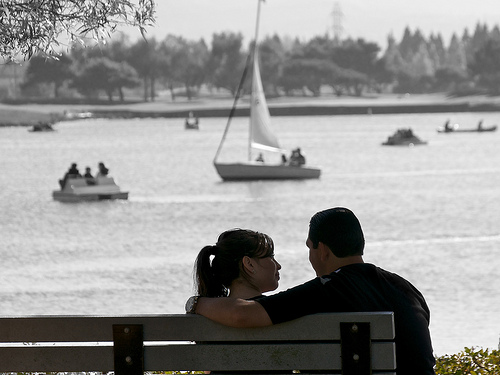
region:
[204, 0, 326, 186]
a few people in a sailboat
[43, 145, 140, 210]
three people in a paddleboat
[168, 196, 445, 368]
two people talking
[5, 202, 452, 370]
two people sitting on a bench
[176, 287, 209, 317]
a very large watch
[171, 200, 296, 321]
a woman wearing her hair in a pony tail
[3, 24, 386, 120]
many low trees with flat tops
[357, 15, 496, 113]
pointy triangular evergreen trees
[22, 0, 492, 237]
six boats on a sparkly lake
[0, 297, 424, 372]
a long park bench by a lake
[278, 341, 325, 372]
part of a bench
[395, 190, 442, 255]
part of a water body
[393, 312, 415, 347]
part of a black top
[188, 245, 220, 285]
hair of a woman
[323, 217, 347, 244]
hair of a man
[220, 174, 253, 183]
base of a boat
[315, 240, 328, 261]
left ear of a man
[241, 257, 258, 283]
right ear of the lady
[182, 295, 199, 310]
part of a wrist watch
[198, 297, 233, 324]
left arm of the man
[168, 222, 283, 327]
the woman is gazing at the man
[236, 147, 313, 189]
there are 4 people on the sailboat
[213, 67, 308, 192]
there is a sailboat on the water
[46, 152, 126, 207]
these people are in a paddle boat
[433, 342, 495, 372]
the bush is near the couple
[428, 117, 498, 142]
there are two people rowing the canoe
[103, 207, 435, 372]
the couple is sitting on a bench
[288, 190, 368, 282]
the man is looking out over the water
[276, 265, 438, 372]
the man is wearing a black shirt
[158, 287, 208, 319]
the man is wearing a big watch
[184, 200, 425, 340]
two people sitting on a bench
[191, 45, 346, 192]
a small sailboat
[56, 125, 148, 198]
three people riding on a boat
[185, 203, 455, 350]
a woman looking at a man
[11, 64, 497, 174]
several boats on the water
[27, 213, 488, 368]
a bench by the water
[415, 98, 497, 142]
two people in a row boat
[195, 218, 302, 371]
a woman with a ponytail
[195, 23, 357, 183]
a boat with people sailing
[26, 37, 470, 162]
multiple trees by the lake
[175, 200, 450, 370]
A couple sitting on a bench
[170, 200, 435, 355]
A man with his arm around a woman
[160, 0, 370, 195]
A sailboat on water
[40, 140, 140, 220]
A group of people in a paddle boat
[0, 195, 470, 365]
A bench facing a body of water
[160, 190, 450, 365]
A woman looking at a man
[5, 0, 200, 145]
Trees alongside water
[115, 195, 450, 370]
A man and woman sitting together on a bench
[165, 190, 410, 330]
A man wearing a watch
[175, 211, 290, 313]
A woman with her hair in a ponytail